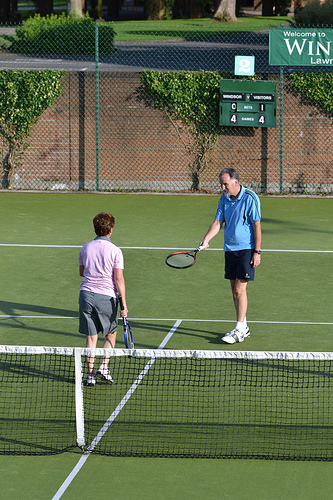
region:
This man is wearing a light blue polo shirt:
[165, 158, 272, 343]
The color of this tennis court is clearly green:
[239, 472, 250, 494]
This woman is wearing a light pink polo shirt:
[69, 210, 127, 332]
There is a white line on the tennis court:
[60, 449, 73, 494]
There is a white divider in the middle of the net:
[56, 346, 102, 495]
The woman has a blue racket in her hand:
[112, 295, 143, 360]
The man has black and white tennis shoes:
[207, 313, 257, 350]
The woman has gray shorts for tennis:
[75, 285, 119, 375]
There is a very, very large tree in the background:
[212, 1, 256, 35]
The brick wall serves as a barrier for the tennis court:
[82, 82, 140, 200]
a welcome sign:
[266, 29, 328, 87]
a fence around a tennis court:
[7, 13, 331, 188]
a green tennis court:
[7, 407, 312, 492]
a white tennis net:
[8, 330, 330, 472]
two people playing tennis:
[73, 147, 283, 349]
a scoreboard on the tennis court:
[218, 51, 290, 140]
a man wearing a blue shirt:
[203, 161, 267, 282]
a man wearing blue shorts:
[192, 163, 286, 315]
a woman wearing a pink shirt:
[63, 206, 179, 358]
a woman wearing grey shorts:
[66, 213, 161, 380]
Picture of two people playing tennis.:
[0, 133, 323, 447]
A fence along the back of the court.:
[49, 30, 184, 189]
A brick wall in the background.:
[69, 70, 203, 187]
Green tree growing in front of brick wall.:
[4, 68, 64, 185]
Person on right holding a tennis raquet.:
[165, 157, 280, 345]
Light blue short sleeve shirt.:
[202, 186, 268, 253]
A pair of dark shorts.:
[217, 246, 270, 291]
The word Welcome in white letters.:
[279, 28, 319, 39]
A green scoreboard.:
[210, 77, 286, 131]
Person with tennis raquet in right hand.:
[66, 199, 140, 358]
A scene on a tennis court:
[18, 150, 306, 483]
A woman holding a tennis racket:
[74, 202, 142, 388]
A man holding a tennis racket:
[162, 160, 295, 345]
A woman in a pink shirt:
[76, 196, 128, 300]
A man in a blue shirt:
[205, 161, 284, 263]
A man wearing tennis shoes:
[208, 150, 269, 345]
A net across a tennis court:
[6, 320, 328, 472]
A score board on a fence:
[208, 51, 303, 144]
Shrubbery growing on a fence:
[10, 66, 205, 156]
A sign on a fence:
[263, 14, 329, 76]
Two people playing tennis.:
[35, 92, 291, 389]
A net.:
[0, 334, 329, 469]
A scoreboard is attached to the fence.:
[206, 71, 279, 136]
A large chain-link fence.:
[10, 20, 302, 206]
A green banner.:
[262, 25, 327, 71]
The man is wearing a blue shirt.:
[152, 166, 264, 349]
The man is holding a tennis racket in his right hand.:
[153, 149, 258, 276]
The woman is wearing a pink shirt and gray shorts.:
[59, 203, 123, 379]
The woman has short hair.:
[83, 202, 119, 242]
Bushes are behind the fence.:
[2, 56, 326, 181]